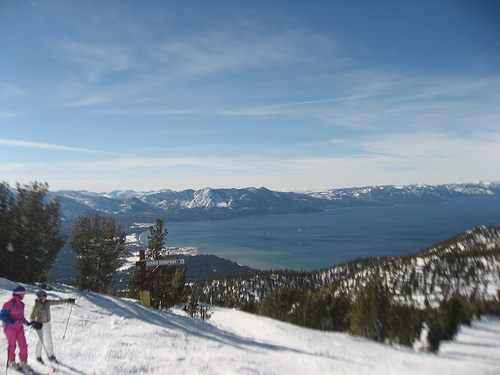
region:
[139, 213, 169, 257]
a tree in a distance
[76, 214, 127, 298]
a tree in a distance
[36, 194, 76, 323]
a tree in a distance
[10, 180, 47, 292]
a tree in a distance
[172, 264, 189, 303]
a tree in a distance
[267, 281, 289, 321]
a tree in a distance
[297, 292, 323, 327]
a tree in a distance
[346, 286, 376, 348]
a tree in a distance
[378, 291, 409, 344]
a tree in a distance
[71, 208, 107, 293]
A tree in a distance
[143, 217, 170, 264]
A tree in a distance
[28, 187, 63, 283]
A tree in a distance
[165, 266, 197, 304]
A tree in a distance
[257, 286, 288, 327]
A tree in a distance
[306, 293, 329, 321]
A tree in a distance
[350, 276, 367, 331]
A tree in a distance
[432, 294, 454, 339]
A tree in a distance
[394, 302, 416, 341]
A tree in a distance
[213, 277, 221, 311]
A tree in a distance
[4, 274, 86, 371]
two women with winter jackets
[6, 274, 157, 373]
two women standing in a ski slope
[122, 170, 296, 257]
large water ocean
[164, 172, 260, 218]
snowy mountain tops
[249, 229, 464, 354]
forest on snowy hill area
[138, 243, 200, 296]
white and blue sign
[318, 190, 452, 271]
blue cold water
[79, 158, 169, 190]
white and blue sky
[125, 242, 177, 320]
wood pole holding a blue sign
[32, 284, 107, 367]
woman pointing to right of the foto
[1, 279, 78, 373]
skiers looking on mountain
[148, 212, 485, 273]
massive waterway in photo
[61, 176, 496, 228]
mountains on horizon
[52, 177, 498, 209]
snow covered mountains in background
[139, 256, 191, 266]
sign pointing out direction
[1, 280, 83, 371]
woman pointing out object to friend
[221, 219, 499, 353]
tree covered mountain side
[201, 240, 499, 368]
ski slopes separated by trees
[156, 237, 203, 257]
beach area at bottom of mountain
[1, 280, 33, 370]
skier in pink outfit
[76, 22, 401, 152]
The sky is blue.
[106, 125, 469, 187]
The clouds are white.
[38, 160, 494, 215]
Mountains in the background.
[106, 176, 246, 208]
Snow covering mountains.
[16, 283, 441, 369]
Snow covering ground.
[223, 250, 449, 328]
Snow covering trees.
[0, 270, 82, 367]
Two people skiing on a mountain.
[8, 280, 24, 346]
Woman wearing pink snow suit.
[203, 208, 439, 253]
The water is in front of mountains.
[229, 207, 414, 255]
The water is blue.